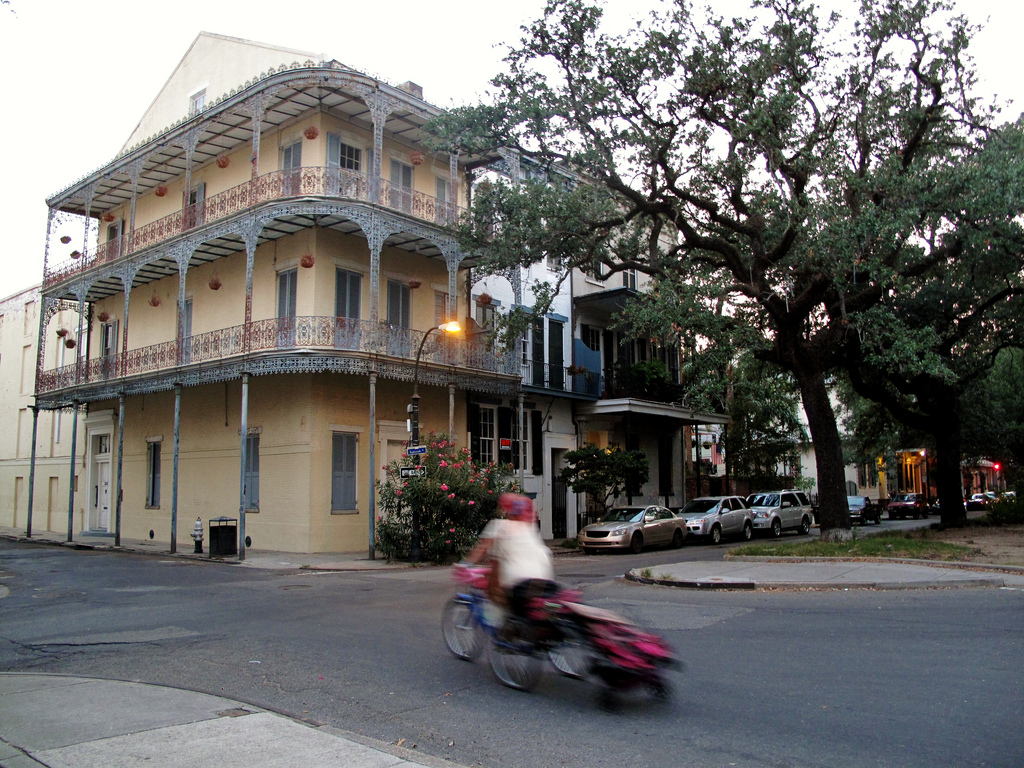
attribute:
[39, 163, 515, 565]
house — multi story 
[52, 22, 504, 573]
house — multi story 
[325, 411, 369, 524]
window — grey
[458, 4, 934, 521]
tree — large 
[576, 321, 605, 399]
wall — blue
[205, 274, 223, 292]
ball — red , Small 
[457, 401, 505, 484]
frame — Black 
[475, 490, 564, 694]
person — small 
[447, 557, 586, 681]
bike — blue 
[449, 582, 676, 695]
motorcycle — red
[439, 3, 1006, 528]
tree — big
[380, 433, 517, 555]
plant — red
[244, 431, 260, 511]
window — gray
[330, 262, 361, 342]
window — gray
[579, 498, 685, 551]
car — Silver 